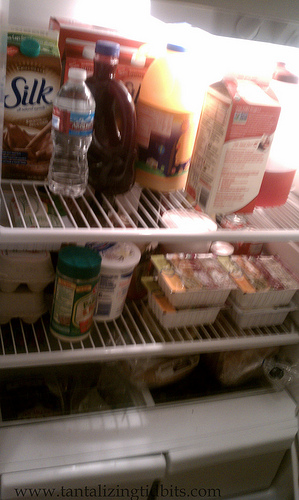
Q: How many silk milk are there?
A: One.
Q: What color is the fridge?
A: White.